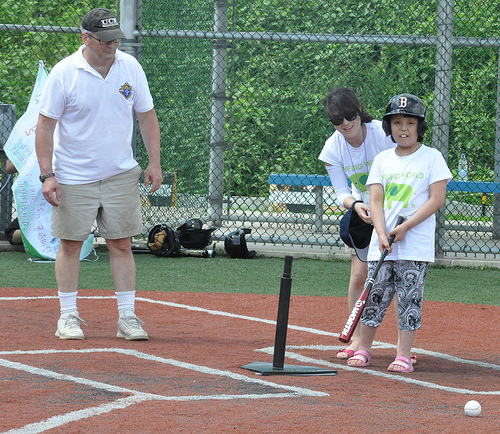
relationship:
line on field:
[114, 345, 326, 397] [8, 240, 497, 432]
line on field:
[1, 355, 151, 400] [8, 240, 497, 432]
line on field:
[1, 342, 118, 357] [8, 240, 497, 432]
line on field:
[1, 395, 153, 431] [8, 240, 497, 432]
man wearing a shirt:
[35, 8, 162, 342] [31, 69, 173, 181]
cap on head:
[81, 8, 127, 42] [81, 5, 127, 64]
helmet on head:
[383, 90, 428, 134] [376, 92, 429, 149]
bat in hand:
[324, 209, 414, 349] [368, 226, 399, 261]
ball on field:
[462, 395, 482, 418] [0, 243, 500, 434]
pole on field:
[273, 255, 294, 371] [8, 240, 497, 432]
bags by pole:
[137, 215, 261, 258] [261, 245, 315, 370]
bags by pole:
[4, 59, 105, 261] [195, 44, 249, 227]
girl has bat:
[345, 93, 453, 375] [337, 216, 404, 343]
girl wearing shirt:
[318, 87, 419, 366] [360, 144, 452, 262]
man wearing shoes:
[20, 4, 178, 359] [39, 301, 159, 347]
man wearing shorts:
[35, 8, 162, 342] [46, 156, 146, 244]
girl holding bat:
[347, 93, 454, 373] [333, 212, 411, 342]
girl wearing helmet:
[317, 86, 394, 359] [380, 94, 428, 122]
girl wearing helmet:
[345, 93, 453, 375] [380, 94, 428, 122]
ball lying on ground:
[464, 400, 482, 417] [4, 251, 499, 432]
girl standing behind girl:
[318, 87, 419, 366] [345, 93, 453, 375]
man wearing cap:
[20, 4, 178, 359] [81, 7, 131, 47]